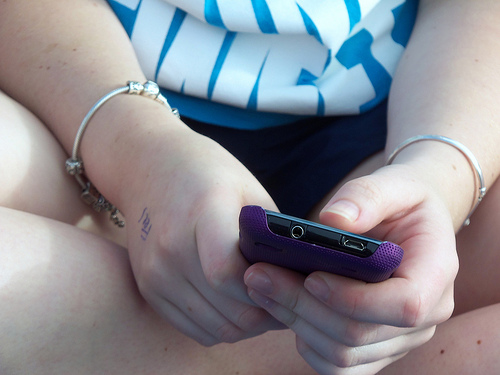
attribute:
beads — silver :
[62, 157, 127, 227]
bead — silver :
[146, 77, 158, 97]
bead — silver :
[143, 78, 160, 101]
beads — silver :
[113, 73, 174, 106]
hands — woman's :
[116, 133, 463, 363]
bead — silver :
[471, 179, 491, 204]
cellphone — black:
[230, 201, 415, 320]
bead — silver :
[59, 155, 87, 179]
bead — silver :
[62, 157, 84, 174]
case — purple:
[238, 204, 403, 278]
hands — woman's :
[100, 132, 475, 371]